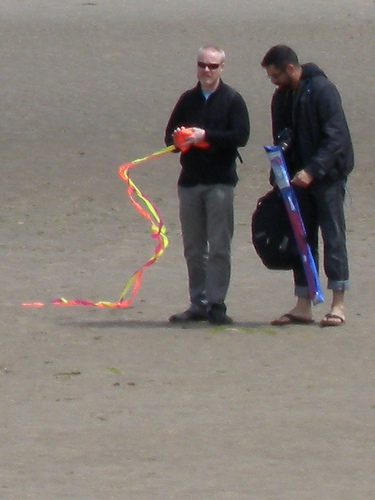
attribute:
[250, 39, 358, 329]
man — standing, young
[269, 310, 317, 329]
sandal — brown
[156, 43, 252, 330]
man — balding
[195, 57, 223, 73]
sunglasses — black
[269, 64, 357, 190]
jacket — black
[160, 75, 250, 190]
sweater — black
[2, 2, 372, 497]
ground — gray sand, cement colored, sand covered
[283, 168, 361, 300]
pants — cuffed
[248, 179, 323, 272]
backpack — black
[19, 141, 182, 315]
ribbon — colorful, yellow, orange, green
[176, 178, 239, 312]
slacks — gray, grey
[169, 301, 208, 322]
sock — black, grey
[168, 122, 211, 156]
toy — orange